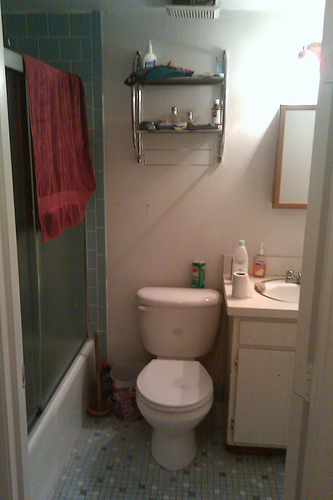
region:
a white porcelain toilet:
[135, 282, 222, 471]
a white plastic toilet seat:
[135, 360, 214, 411]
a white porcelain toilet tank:
[136, 286, 220, 359]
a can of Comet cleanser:
[190, 260, 205, 286]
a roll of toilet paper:
[230, 270, 249, 297]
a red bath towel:
[22, 52, 94, 239]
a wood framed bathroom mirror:
[274, 105, 316, 207]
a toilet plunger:
[86, 329, 113, 415]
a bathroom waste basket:
[109, 363, 144, 421]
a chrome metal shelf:
[130, 46, 224, 165]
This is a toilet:
[132, 355, 220, 478]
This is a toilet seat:
[127, 347, 225, 416]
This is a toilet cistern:
[125, 274, 232, 362]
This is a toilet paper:
[226, 263, 257, 307]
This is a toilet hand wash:
[253, 238, 270, 283]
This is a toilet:
[108, 248, 228, 494]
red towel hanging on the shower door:
[18, 51, 98, 245]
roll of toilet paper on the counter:
[230, 270, 255, 300]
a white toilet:
[134, 284, 224, 472]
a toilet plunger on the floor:
[85, 327, 112, 416]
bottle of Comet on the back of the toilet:
[190, 258, 207, 288]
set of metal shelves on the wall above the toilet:
[129, 37, 228, 166]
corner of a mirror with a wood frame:
[272, 103, 317, 208]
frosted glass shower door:
[4, 46, 90, 439]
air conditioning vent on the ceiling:
[165, 1, 219, 20]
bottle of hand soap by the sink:
[254, 241, 266, 276]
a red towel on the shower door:
[23, 54, 94, 240]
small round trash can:
[110, 364, 142, 419]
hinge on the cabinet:
[230, 417, 234, 429]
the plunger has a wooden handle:
[87, 331, 112, 417]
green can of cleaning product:
[192, 260, 204, 287]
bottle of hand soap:
[254, 241, 266, 276]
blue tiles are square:
[56, 410, 284, 497]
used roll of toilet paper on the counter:
[232, 270, 251, 298]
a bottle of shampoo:
[232, 240, 246, 277]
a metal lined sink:
[252, 278, 301, 305]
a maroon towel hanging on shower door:
[18, 48, 96, 243]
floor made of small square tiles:
[50, 396, 288, 499]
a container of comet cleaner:
[190, 257, 208, 289]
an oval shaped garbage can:
[108, 360, 145, 427]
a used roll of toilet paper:
[230, 269, 251, 300]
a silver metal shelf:
[127, 32, 224, 166]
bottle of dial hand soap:
[252, 239, 269, 276]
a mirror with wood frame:
[271, 101, 317, 211]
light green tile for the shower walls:
[2, 7, 105, 371]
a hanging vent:
[160, 0, 222, 24]